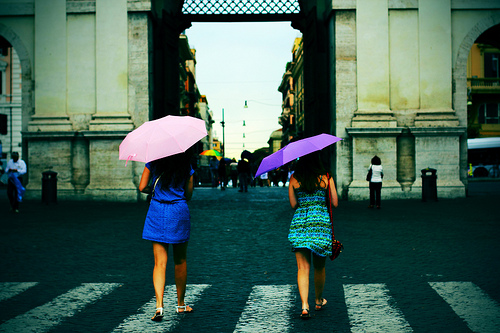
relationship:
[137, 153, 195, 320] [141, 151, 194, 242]
person wearing dress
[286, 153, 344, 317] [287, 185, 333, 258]
person wearing dress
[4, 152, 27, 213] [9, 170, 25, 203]
man wearing blue jeans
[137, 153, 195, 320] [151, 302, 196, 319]
person wearing sandals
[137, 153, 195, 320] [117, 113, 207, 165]
person holding umbrella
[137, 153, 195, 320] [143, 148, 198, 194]
person has hair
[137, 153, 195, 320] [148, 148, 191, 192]
person has hair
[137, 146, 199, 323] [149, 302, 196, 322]
person wearing sandals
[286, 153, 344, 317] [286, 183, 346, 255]
person wearing dress.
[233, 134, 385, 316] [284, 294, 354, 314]
person on sandals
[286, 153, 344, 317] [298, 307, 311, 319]
person on sandal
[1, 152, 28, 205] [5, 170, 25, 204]
man on blue jeans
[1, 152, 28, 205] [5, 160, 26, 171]
man on shirt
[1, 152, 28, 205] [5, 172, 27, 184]
man on bench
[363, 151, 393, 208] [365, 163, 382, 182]
woman on shirt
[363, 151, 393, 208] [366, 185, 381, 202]
woman on pants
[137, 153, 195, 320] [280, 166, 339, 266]
person wearing dress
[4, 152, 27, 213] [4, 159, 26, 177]
man carrying coat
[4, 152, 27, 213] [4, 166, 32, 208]
man carrying coat